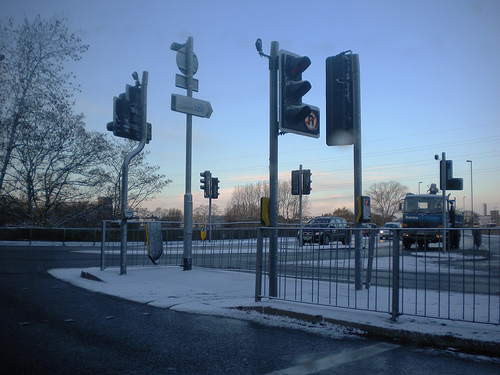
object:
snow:
[46, 262, 499, 362]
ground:
[0, 239, 500, 375]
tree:
[0, 8, 87, 205]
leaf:
[35, 15, 39, 17]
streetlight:
[277, 52, 310, 135]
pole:
[267, 37, 277, 305]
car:
[297, 216, 352, 248]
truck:
[401, 193, 462, 250]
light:
[402, 232, 410, 237]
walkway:
[2, 296, 112, 332]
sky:
[1, 0, 499, 218]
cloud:
[160, 197, 180, 207]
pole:
[118, 72, 152, 274]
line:
[270, 332, 402, 374]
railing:
[255, 226, 500, 326]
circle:
[305, 111, 319, 131]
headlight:
[314, 231, 324, 235]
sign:
[176, 47, 200, 76]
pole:
[183, 37, 192, 271]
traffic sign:
[259, 199, 276, 228]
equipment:
[428, 183, 439, 196]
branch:
[38, 34, 44, 58]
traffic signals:
[257, 35, 320, 139]